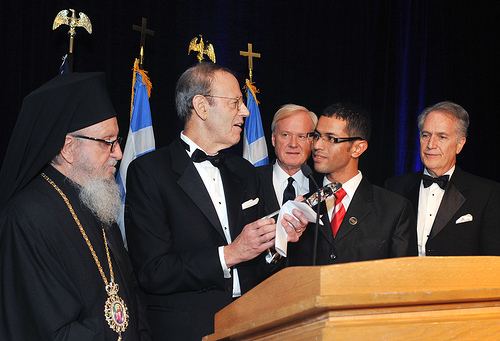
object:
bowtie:
[190, 146, 223, 168]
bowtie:
[419, 171, 451, 192]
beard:
[68, 148, 124, 226]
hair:
[320, 97, 373, 143]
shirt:
[178, 130, 245, 297]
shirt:
[406, 161, 460, 261]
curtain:
[3, 1, 499, 204]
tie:
[328, 188, 347, 243]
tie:
[281, 177, 301, 208]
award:
[252, 174, 345, 268]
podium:
[195, 249, 498, 339]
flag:
[115, 62, 163, 252]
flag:
[241, 77, 273, 177]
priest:
[3, 67, 153, 339]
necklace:
[41, 165, 135, 340]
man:
[119, 59, 302, 339]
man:
[375, 96, 497, 258]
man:
[277, 98, 419, 273]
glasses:
[198, 94, 245, 109]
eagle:
[47, 5, 94, 37]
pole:
[65, 26, 76, 73]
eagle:
[182, 29, 217, 63]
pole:
[195, 53, 204, 67]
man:
[253, 98, 323, 286]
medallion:
[101, 282, 132, 334]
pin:
[346, 214, 358, 228]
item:
[273, 196, 323, 257]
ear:
[190, 91, 211, 122]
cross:
[235, 43, 264, 78]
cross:
[127, 15, 160, 62]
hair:
[268, 99, 320, 127]